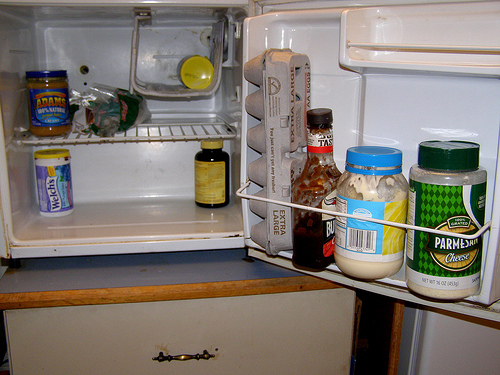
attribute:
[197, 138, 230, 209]
vitamins — on the shelf, black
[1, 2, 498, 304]
fridge — small, open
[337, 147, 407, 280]
mayonnaise — in a jar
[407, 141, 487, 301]
parmesan cheese — in a jar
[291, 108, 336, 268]
barbeque sauce — in a bottle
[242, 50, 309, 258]
eggs — in a carton, standing up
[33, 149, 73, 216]
welch's drink — in a container, on bottom shelf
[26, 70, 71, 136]
sauce — yellow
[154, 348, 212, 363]
handle — metal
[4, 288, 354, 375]
drawer — white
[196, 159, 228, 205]
label — yellow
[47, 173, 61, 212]
letters — purple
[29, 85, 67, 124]
label — blue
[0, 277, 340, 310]
seal — wooden